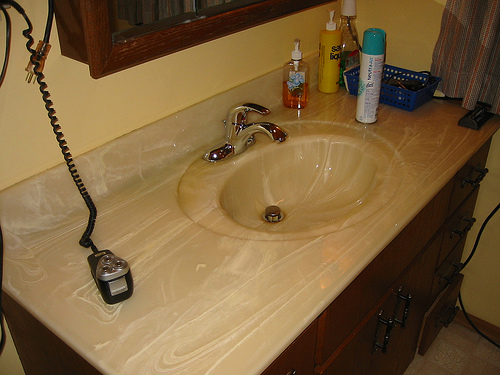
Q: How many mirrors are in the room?
A: One.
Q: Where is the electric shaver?
A: Counter.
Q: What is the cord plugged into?
A: Socket.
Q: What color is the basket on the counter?
A: Blue.